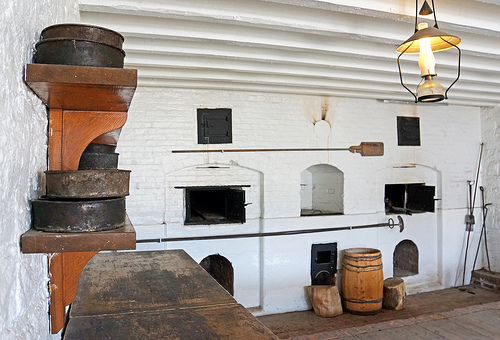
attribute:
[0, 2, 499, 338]
bakery — old, antique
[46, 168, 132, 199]
pan — used to shape bread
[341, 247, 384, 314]
barrel — wooden, large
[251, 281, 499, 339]
floor — wooden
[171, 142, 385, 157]
tool — wooden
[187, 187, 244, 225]
oven — open, small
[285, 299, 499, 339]
rug — matted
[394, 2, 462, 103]
lamp — old, hanging, hung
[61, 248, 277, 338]
table — wooden, on the left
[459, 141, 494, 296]
tools — metal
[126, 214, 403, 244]
rod — hanging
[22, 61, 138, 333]
shelves — wooden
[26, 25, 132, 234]
pans — circular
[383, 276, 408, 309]
stump — on the right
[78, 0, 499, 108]
beams — exposed